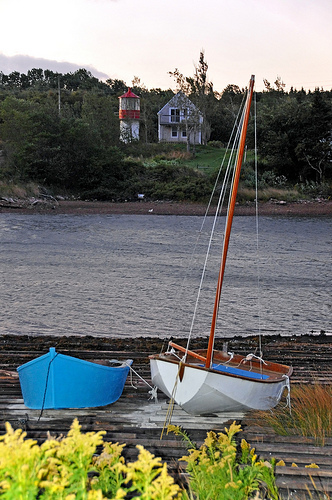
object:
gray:
[160, 99, 201, 143]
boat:
[145, 72, 295, 419]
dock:
[0, 324, 332, 443]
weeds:
[245, 381, 331, 451]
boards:
[0, 330, 331, 490]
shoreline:
[3, 206, 332, 221]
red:
[120, 86, 139, 104]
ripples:
[4, 211, 47, 239]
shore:
[0, 198, 331, 219]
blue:
[0, 204, 128, 325]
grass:
[268, 180, 303, 200]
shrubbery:
[1, 109, 125, 195]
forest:
[0, 66, 332, 198]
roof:
[158, 88, 199, 113]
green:
[194, 49, 212, 81]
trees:
[166, 47, 213, 157]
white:
[0, 0, 331, 93]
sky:
[1, 2, 332, 90]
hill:
[0, 62, 332, 140]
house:
[117, 82, 144, 147]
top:
[118, 84, 141, 101]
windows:
[118, 99, 127, 108]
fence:
[117, 106, 141, 123]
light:
[61, 80, 69, 93]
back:
[0, 64, 321, 200]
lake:
[0, 210, 332, 339]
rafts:
[15, 342, 137, 413]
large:
[156, 72, 268, 371]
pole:
[203, 71, 257, 372]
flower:
[305, 459, 327, 497]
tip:
[162, 419, 195, 453]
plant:
[166, 424, 279, 500]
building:
[154, 85, 208, 143]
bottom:
[161, 389, 246, 417]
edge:
[1, 206, 330, 219]